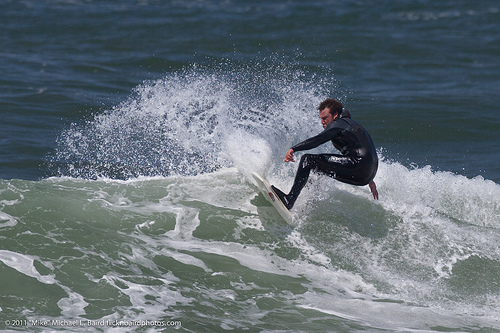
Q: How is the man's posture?
A: Crouching man over water.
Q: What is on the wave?
A: White seafoam on wave.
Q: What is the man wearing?
A: Black wetsuit on man.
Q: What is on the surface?
A: Ripples on water surface.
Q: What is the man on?
A: A surfboard.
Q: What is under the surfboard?
A: Waves.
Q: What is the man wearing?
A: A wet suit.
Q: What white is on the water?
A: Foam.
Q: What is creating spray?
A: Crashing waves.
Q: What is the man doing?
A: Surfing.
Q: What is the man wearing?
A: A wetsuit.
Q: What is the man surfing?
A: A wave.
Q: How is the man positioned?
A: Hunched over.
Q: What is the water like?
A: Green.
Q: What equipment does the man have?
A: A surfboard.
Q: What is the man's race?
A: White.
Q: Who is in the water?
A: The surfer.